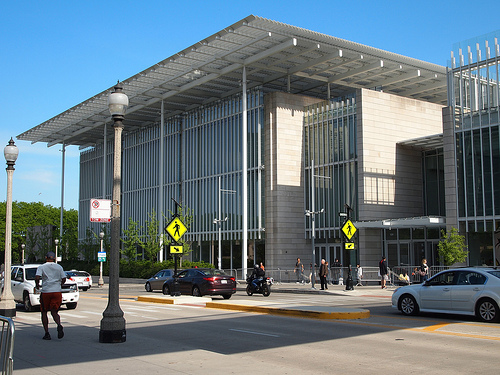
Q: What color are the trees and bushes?
A: Green.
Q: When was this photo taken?
A: During the day.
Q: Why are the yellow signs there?
A: To tell cars to watch for pedestrians.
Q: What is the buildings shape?
A: Square.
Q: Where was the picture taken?
A: Outside of a large building.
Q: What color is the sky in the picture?
A: Blue.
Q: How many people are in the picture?
A: Nine.